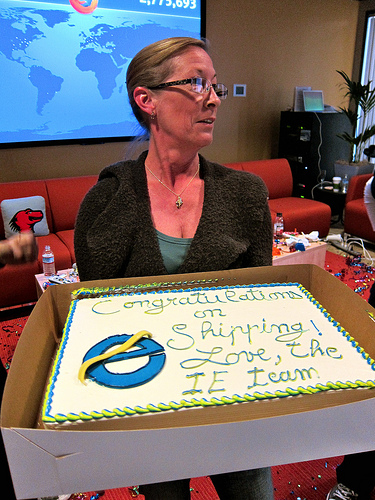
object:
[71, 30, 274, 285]
lady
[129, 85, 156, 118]
ear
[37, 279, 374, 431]
cake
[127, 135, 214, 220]
necklace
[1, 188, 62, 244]
pillow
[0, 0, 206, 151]
map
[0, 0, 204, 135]
screen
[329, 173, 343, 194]
cup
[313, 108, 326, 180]
wires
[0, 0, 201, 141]
picture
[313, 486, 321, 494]
confetti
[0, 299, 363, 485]
carpet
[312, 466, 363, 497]
shoe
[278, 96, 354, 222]
cabinet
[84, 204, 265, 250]
sweater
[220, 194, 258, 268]
grey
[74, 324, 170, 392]
letter e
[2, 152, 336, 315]
couch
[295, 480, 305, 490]
confetti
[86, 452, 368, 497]
floor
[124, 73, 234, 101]
glasses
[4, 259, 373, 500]
box